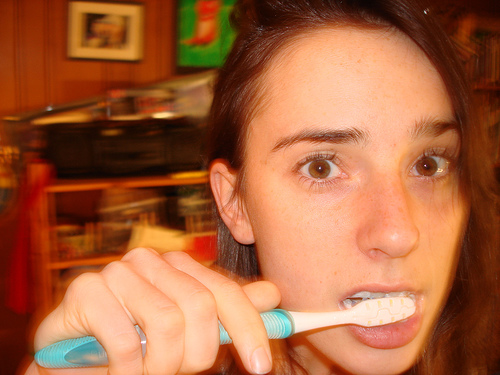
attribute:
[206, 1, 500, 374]
hair — black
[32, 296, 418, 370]
toothbrush — white, blue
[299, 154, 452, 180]
eyes — hazel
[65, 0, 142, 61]
frame — black, white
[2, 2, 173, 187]
wall — brown, wooden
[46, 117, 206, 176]
radio — black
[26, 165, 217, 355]
cabinet — brown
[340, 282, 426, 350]
mouth — open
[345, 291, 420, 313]
teeth — white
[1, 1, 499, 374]
photo — blurr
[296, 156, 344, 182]
right eye — open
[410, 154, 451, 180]
left eye — open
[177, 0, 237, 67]
painting — green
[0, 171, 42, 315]
dress — red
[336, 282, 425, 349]
lips — pink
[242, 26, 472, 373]
face — oval